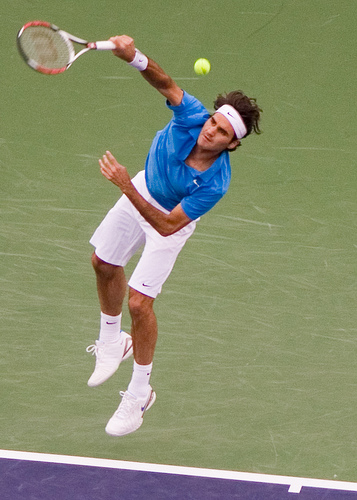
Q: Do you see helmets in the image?
A: No, there are no helmets.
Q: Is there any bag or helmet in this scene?
A: No, there are no helmets or bags.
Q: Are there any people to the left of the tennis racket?
A: No, the person is to the right of the tennis racket.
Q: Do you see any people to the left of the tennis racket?
A: No, the person is to the right of the tennis racket.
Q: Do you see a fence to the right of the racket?
A: No, there is a person to the right of the racket.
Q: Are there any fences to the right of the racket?
A: No, there is a person to the right of the racket.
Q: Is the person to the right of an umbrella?
A: No, the person is to the right of the racket.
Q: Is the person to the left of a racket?
A: No, the person is to the right of a racket.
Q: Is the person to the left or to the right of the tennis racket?
A: The person is to the right of the tennis racket.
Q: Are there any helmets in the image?
A: No, there are no helmets.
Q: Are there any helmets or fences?
A: No, there are no helmets or fences.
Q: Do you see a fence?
A: No, there are no fences.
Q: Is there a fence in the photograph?
A: No, there are no fences.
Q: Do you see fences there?
A: No, there are no fences.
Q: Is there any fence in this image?
A: No, there are no fences.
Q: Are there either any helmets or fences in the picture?
A: No, there are no fences or helmets.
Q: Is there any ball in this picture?
A: Yes, there is a ball.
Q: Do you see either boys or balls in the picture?
A: Yes, there is a ball.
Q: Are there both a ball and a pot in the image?
A: No, there is a ball but no pots.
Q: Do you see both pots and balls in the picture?
A: No, there is a ball but no pots.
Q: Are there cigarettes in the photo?
A: No, there are no cigarettes.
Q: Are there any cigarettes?
A: No, there are no cigarettes.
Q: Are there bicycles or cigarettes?
A: No, there are no cigarettes or bicycles.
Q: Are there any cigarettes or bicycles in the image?
A: No, there are no cigarettes or bicycles.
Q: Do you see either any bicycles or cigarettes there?
A: No, there are no cigarettes or bicycles.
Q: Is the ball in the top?
A: Yes, the ball is in the top of the image.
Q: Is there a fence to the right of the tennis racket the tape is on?
A: No, there is a ball to the right of the tennis racket.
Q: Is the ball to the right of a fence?
A: No, the ball is to the right of a racket.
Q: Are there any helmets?
A: No, there are no helmets.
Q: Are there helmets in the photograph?
A: No, there are no helmets.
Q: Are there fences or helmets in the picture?
A: No, there are no helmets or fences.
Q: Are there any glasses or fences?
A: No, there are no fences or glasses.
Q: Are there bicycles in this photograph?
A: No, there are no bicycles.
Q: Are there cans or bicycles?
A: No, there are no bicycles or cans.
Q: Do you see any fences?
A: No, there are no fences.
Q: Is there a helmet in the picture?
A: No, there are no helmets.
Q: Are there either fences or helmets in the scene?
A: No, there are no helmets or fences.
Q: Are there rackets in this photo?
A: Yes, there is a racket.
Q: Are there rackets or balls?
A: Yes, there is a racket.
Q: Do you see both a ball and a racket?
A: Yes, there are both a racket and a ball.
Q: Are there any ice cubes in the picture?
A: No, there are no ice cubes.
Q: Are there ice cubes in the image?
A: No, there are no ice cubes.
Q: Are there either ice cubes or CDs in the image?
A: No, there are no ice cubes or cds.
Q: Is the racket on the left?
A: Yes, the racket is on the left of the image.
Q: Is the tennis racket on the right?
A: No, the tennis racket is on the left of the image.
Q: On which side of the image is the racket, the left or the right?
A: The racket is on the left of the image.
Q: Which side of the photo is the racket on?
A: The racket is on the left of the image.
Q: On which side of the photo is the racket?
A: The racket is on the left of the image.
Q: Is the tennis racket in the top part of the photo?
A: Yes, the tennis racket is in the top of the image.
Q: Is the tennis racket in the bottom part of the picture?
A: No, the tennis racket is in the top of the image.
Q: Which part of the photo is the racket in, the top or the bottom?
A: The racket is in the top of the image.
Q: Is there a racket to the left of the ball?
A: Yes, there is a racket to the left of the ball.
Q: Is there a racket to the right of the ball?
A: No, the racket is to the left of the ball.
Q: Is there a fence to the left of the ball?
A: No, there is a racket to the left of the ball.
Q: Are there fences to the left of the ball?
A: No, there is a racket to the left of the ball.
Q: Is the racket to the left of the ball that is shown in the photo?
A: Yes, the racket is to the left of the ball.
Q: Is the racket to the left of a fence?
A: No, the racket is to the left of the ball.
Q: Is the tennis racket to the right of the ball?
A: No, the tennis racket is to the left of the ball.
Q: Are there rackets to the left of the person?
A: Yes, there is a racket to the left of the person.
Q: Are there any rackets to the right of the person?
A: No, the racket is to the left of the person.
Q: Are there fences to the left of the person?
A: No, there is a racket to the left of the person.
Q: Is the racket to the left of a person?
A: Yes, the racket is to the left of a person.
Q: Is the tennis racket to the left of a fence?
A: No, the tennis racket is to the left of a person.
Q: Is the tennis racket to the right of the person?
A: No, the tennis racket is to the left of the person.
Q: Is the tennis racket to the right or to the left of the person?
A: The tennis racket is to the left of the person.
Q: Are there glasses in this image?
A: No, there are no glasses.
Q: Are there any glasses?
A: No, there are no glasses.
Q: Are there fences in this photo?
A: No, there are no fences.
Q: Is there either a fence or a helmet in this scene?
A: No, there are no fences or helmets.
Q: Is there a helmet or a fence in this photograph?
A: No, there are no fences or helmets.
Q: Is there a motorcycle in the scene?
A: No, there are no motorcycles.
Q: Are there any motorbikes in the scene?
A: No, there are no motorbikes.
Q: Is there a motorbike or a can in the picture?
A: No, there are no motorcycles or cans.